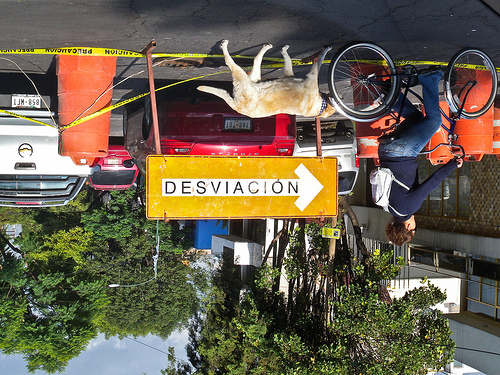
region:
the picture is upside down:
[8, 7, 481, 369]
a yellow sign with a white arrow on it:
[138, 135, 349, 229]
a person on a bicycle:
[326, 33, 491, 250]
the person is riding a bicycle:
[326, 37, 495, 259]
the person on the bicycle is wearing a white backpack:
[328, 30, 498, 252]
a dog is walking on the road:
[197, 30, 354, 124]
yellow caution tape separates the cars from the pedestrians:
[1, 34, 498, 129]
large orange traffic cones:
[42, 40, 498, 176]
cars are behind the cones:
[5, 67, 472, 219]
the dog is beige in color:
[196, 37, 346, 127]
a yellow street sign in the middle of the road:
[141, 152, 338, 223]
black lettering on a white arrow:
[163, 173, 311, 198]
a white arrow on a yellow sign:
[161, 160, 326, 210]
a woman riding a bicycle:
[341, 30, 481, 249]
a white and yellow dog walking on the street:
[208, 33, 339, 129]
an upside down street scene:
[1, 13, 487, 367]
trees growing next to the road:
[1, 176, 452, 361]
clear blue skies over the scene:
[86, 344, 166, 374]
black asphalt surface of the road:
[116, 0, 221, 44]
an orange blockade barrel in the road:
[39, 43, 125, 178]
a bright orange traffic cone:
[51, 48, 120, 169]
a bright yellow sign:
[143, 150, 340, 223]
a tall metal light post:
[103, 218, 160, 290]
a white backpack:
[366, 165, 398, 213]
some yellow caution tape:
[2, 41, 142, 61]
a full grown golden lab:
[200, 45, 347, 119]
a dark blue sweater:
[374, 157, 457, 221]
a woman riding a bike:
[328, 45, 496, 247]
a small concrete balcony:
[209, 233, 261, 271]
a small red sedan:
[119, 100, 298, 181]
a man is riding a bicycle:
[332, 36, 489, 273]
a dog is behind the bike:
[176, 25, 338, 123]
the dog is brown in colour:
[198, 45, 335, 138]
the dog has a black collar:
[161, 38, 348, 120]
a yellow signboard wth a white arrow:
[121, 133, 337, 225]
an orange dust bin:
[39, 29, 127, 176]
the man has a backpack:
[360, 146, 440, 227]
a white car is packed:
[4, 105, 95, 203]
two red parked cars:
[98, 108, 284, 195]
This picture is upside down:
[58, 19, 456, 268]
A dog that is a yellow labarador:
[196, 32, 346, 124]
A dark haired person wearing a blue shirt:
[358, 124, 460, 276]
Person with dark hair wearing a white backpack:
[367, 153, 460, 246]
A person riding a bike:
[343, 42, 497, 259]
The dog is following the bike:
[201, 29, 472, 217]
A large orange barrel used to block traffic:
[48, 44, 117, 180]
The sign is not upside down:
[146, 142, 349, 232]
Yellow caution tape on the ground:
[27, 44, 189, 67]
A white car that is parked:
[1, 89, 90, 226]